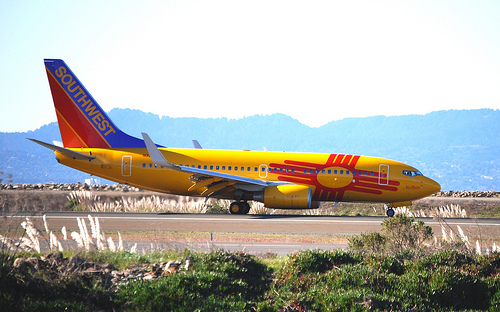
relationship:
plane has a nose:
[24, 58, 442, 218] [434, 181, 443, 196]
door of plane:
[378, 162, 390, 188] [24, 58, 442, 218]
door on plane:
[378, 162, 390, 188] [24, 58, 442, 218]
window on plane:
[370, 168, 374, 176] [24, 58, 442, 218]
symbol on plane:
[53, 63, 116, 138] [24, 58, 442, 218]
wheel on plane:
[228, 201, 243, 215] [24, 58, 442, 218]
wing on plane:
[141, 130, 299, 199] [24, 58, 442, 218]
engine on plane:
[249, 183, 313, 210] [24, 58, 442, 218]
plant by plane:
[81, 193, 227, 215] [24, 58, 442, 218]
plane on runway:
[24, 58, 442, 218] [1, 209, 499, 226]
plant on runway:
[81, 193, 227, 215] [1, 209, 499, 226]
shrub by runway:
[345, 211, 437, 260] [1, 209, 499, 226]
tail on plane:
[42, 55, 127, 189] [24, 58, 442, 218]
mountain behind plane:
[32, 105, 311, 184] [24, 58, 442, 218]